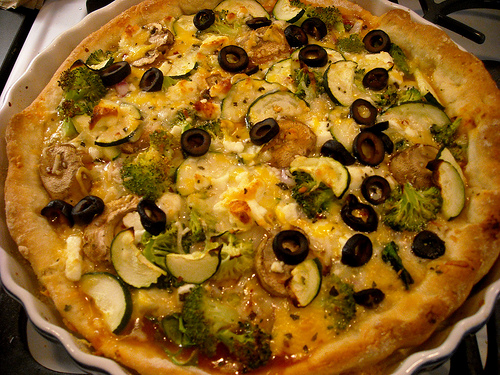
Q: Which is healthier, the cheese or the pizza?
A: The cheese is healthier than the pizza.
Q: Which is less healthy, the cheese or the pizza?
A: The pizza is less healthy than the cheese.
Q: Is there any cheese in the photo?
A: Yes, there is cheese.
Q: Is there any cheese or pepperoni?
A: Yes, there is cheese.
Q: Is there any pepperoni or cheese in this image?
A: Yes, there is cheese.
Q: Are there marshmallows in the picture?
A: No, there are no marshmallows.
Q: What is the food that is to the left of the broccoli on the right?
A: The food is cheese.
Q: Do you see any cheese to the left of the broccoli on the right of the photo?
A: Yes, there is cheese to the left of the broccoli.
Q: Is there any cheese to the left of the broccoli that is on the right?
A: Yes, there is cheese to the left of the broccoli.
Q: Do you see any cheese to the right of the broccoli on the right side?
A: No, the cheese is to the left of the broccoli.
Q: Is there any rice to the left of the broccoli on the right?
A: No, there is cheese to the left of the broccoli.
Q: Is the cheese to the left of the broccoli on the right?
A: Yes, the cheese is to the left of the broccoli.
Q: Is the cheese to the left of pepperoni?
A: No, the cheese is to the left of the broccoli.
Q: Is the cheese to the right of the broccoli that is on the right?
A: No, the cheese is to the left of the broccoli.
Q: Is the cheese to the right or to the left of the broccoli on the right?
A: The cheese is to the left of the broccoli.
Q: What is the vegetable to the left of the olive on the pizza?
A: The vegetable is a squash.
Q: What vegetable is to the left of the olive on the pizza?
A: The vegetable is a squash.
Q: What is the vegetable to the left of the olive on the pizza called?
A: The vegetable is a squash.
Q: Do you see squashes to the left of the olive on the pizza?
A: Yes, there is a squash to the left of the olive.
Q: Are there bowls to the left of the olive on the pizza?
A: No, there is a squash to the left of the olive.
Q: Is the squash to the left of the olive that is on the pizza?
A: Yes, the squash is to the left of the olive.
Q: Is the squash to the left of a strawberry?
A: No, the squash is to the left of the olive.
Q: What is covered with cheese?
A: The squash is covered with cheese.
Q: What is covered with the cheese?
A: The squash is covered with cheese.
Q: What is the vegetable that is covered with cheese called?
A: The vegetable is a squash.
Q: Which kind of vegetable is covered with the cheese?
A: The vegetable is a squash.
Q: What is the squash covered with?
A: The squash is covered with cheese.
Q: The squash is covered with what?
A: The squash is covered with cheese.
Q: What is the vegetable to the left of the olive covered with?
A: The squash is covered with cheese.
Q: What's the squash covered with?
A: The squash is covered with cheese.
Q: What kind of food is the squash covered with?
A: The squash is covered with cheese.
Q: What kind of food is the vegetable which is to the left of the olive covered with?
A: The squash is covered with cheese.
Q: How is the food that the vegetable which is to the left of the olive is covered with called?
A: The food is cheese.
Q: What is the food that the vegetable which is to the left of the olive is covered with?
A: The food is cheese.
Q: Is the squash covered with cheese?
A: Yes, the squash is covered with cheese.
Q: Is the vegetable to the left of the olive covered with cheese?
A: Yes, the squash is covered with cheese.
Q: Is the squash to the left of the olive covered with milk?
A: No, the squash is covered with cheese.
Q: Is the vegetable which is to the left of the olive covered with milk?
A: No, the squash is covered with cheese.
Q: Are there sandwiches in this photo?
A: No, there are no sandwiches.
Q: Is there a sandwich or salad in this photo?
A: No, there are no sandwiches or salad.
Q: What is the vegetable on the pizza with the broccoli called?
A: The vegetable is an olive.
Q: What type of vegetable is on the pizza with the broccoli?
A: The vegetable is an olive.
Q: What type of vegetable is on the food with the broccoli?
A: The vegetable is an olive.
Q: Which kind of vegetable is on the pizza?
A: The vegetable is an olive.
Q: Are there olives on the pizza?
A: Yes, there is an olive on the pizza.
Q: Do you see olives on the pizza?
A: Yes, there is an olive on the pizza.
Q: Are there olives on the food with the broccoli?
A: Yes, there is an olive on the pizza.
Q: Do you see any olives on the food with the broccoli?
A: Yes, there is an olive on the pizza.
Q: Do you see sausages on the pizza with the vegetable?
A: No, there is an olive on the pizza.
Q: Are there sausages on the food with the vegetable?
A: No, there is an olive on the pizza.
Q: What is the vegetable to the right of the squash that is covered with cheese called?
A: The vegetable is an olive.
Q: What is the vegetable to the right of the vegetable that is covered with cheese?
A: The vegetable is an olive.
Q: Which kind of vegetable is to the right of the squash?
A: The vegetable is an olive.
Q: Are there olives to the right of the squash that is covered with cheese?
A: Yes, there is an olive to the right of the squash.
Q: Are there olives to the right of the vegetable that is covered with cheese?
A: Yes, there is an olive to the right of the squash.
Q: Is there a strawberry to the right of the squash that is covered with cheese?
A: No, there is an olive to the right of the squash.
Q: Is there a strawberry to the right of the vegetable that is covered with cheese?
A: No, there is an olive to the right of the squash.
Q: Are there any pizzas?
A: Yes, there is a pizza.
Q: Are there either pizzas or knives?
A: Yes, there is a pizza.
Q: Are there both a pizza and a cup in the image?
A: No, there is a pizza but no cups.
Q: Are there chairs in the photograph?
A: No, there are no chairs.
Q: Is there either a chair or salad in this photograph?
A: No, there are no chairs or salad.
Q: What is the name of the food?
A: The food is a pizza.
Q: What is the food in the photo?
A: The food is a pizza.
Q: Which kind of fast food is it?
A: The food is a pizza.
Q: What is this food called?
A: That is a pizza.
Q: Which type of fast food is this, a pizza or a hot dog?
A: That is a pizza.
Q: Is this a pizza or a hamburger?
A: This is a pizza.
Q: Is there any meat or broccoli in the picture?
A: Yes, there is broccoli.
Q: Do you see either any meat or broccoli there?
A: Yes, there is broccoli.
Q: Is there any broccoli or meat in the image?
A: Yes, there is broccoli.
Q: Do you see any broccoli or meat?
A: Yes, there is broccoli.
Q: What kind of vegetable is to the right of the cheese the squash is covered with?
A: The vegetable is broccoli.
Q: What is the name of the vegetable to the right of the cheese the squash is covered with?
A: The vegetable is broccoli.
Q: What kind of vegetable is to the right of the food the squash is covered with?
A: The vegetable is broccoli.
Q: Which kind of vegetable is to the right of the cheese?
A: The vegetable is broccoli.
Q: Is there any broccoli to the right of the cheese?
A: Yes, there is broccoli to the right of the cheese.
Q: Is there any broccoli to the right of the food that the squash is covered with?
A: Yes, there is broccoli to the right of the cheese.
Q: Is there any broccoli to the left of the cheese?
A: No, the broccoli is to the right of the cheese.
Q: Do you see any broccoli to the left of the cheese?
A: No, the broccoli is to the right of the cheese.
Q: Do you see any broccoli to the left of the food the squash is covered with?
A: No, the broccoli is to the right of the cheese.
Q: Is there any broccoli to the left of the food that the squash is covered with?
A: No, the broccoli is to the right of the cheese.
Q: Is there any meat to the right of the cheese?
A: No, there is broccoli to the right of the cheese.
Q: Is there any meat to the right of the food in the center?
A: No, there is broccoli to the right of the cheese.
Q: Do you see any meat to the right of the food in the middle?
A: No, there is broccoli to the right of the cheese.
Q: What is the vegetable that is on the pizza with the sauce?
A: The vegetable is broccoli.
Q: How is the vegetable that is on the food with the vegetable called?
A: The vegetable is broccoli.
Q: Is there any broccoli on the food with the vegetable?
A: Yes, there is broccoli on the pizza.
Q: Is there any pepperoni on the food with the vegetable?
A: No, there is broccoli on the pizza.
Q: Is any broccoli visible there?
A: Yes, there is broccoli.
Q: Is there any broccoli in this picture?
A: Yes, there is broccoli.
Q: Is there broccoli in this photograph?
A: Yes, there is broccoli.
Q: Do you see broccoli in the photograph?
A: Yes, there is broccoli.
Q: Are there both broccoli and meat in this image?
A: No, there is broccoli but no meat.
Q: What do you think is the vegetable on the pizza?
A: The vegetable is broccoli.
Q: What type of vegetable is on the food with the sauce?
A: The vegetable is broccoli.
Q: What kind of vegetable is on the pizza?
A: The vegetable is broccoli.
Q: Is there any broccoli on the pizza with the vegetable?
A: Yes, there is broccoli on the pizza.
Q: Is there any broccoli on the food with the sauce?
A: Yes, there is broccoli on the pizza.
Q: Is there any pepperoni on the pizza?
A: No, there is broccoli on the pizza.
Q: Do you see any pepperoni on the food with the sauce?
A: No, there is broccoli on the pizza.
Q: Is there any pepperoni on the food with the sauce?
A: No, there is broccoli on the pizza.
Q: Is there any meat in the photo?
A: No, there is no meat.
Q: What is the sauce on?
A: The sauce is on the pizza.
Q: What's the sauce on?
A: The sauce is on the pizza.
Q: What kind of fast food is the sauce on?
A: The sauce is on the pizza.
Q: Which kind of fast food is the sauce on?
A: The sauce is on the pizza.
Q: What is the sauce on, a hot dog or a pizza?
A: The sauce is on a pizza.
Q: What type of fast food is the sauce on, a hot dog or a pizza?
A: The sauce is on a pizza.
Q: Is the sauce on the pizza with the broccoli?
A: Yes, the sauce is on the pizza.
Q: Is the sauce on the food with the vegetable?
A: Yes, the sauce is on the pizza.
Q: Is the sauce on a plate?
A: No, the sauce is on the pizza.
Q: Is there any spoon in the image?
A: No, there are no spoons.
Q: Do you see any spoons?
A: No, there are no spoons.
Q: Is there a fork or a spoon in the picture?
A: No, there are no spoons or forks.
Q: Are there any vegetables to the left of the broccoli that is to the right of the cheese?
A: No, the vegetable is to the right of the broccoli.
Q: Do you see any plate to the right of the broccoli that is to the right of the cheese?
A: No, there is a vegetable to the right of the broccoli.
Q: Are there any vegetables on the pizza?
A: Yes, there is a vegetable on the pizza.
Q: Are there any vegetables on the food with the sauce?
A: Yes, there is a vegetable on the pizza.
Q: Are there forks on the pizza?
A: No, there is a vegetable on the pizza.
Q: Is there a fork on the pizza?
A: No, there is a vegetable on the pizza.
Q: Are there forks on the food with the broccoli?
A: No, there is a vegetable on the pizza.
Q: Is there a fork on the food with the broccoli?
A: No, there is a vegetable on the pizza.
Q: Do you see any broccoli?
A: Yes, there is broccoli.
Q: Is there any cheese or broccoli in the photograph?
A: Yes, there is broccoli.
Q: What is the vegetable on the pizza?
A: The vegetable is broccoli.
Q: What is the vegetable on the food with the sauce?
A: The vegetable is broccoli.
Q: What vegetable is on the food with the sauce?
A: The vegetable is broccoli.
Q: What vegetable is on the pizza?
A: The vegetable is broccoli.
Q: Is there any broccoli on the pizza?
A: Yes, there is broccoli on the pizza.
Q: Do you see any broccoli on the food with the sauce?
A: Yes, there is broccoli on the pizza.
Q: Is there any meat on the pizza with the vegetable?
A: No, there is broccoli on the pizza.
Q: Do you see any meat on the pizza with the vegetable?
A: No, there is broccoli on the pizza.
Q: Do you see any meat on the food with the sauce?
A: No, there is broccoli on the pizza.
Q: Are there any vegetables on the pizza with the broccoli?
A: Yes, there is a vegetable on the pizza.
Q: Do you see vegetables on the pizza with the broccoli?
A: Yes, there is a vegetable on the pizza.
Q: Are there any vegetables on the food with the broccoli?
A: Yes, there is a vegetable on the pizza.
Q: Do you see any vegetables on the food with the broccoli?
A: Yes, there is a vegetable on the pizza.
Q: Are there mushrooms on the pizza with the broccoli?
A: No, there is a vegetable on the pizza.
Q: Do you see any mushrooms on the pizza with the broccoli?
A: No, there is a vegetable on the pizza.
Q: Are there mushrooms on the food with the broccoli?
A: No, there is a vegetable on the pizza.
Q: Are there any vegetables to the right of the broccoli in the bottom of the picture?
A: Yes, there is a vegetable to the right of the broccoli.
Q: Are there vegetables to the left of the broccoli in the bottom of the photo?
A: No, the vegetable is to the right of the broccoli.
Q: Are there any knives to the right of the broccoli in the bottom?
A: No, there is a vegetable to the right of the broccoli.